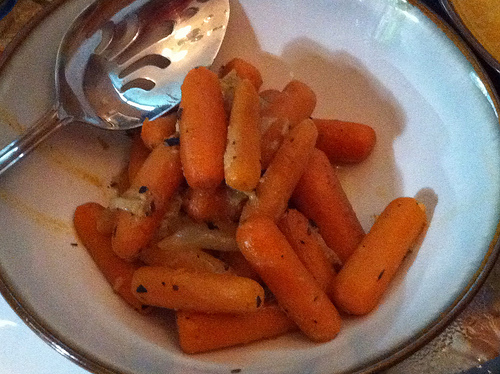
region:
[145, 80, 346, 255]
food in a bowl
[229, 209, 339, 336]
orange pieces of food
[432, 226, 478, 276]
bowl next to food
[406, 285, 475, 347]
rim of the bowl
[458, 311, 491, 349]
table under the bowl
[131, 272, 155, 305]
item on the food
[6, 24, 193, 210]
spoon in the bowl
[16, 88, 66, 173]
handle of the spoon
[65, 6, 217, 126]
top of the spoon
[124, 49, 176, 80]
hole in the spoon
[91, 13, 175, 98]
Small holes in the shiny metal spoon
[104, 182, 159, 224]
Onions draped over the baby carrots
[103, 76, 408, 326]
A number of orange baby carrots in a white bowl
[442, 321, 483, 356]
Water condensing around the hot bowl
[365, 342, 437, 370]
The thin metal trim of the white bowl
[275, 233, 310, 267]
Black pepper on the baby carrots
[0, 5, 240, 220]
A shiny metal spoon in the bowl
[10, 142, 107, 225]
Streaks of food on the white bowl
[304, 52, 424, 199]
A black shadow by the carrots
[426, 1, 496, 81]
A utensil on the table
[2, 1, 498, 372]
The plate is white.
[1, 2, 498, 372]
The plate is round.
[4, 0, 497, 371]
The plate is in use.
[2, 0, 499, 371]
Carrots are on the plate.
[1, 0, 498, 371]
The carrots are orange.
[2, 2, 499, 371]
The carrots are cooked.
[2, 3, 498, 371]
The carrots are whole baby carrots.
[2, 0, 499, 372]
A spoon is on the plate.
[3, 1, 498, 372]
The spoon is silver.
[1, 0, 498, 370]
The spoon is a serving spoon.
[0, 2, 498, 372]
carrots. at home. w/ stuff on them.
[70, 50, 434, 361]
carrots are cooked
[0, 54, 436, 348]
carrots are sauced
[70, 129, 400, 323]
sauce is savory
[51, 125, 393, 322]
flecks of different spices in sauce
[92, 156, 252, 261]
unlike a lot of carrot sauces this one is not sweet, it has onions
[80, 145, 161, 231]
onions are finely diced.....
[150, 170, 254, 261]
.....or, occasionally, thickly chopped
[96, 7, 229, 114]
lights reflected in slotted ladle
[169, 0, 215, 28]
photographer's face, i think, reflected in ladle too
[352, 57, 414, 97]
part of a shade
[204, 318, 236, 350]
part of a carrot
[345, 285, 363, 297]
edge fo a carrot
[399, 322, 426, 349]
edge of a bowl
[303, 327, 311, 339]
part of a carrot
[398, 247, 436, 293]
part of a shade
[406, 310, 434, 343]
dge fo a boawl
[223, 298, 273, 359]
part of a carrot